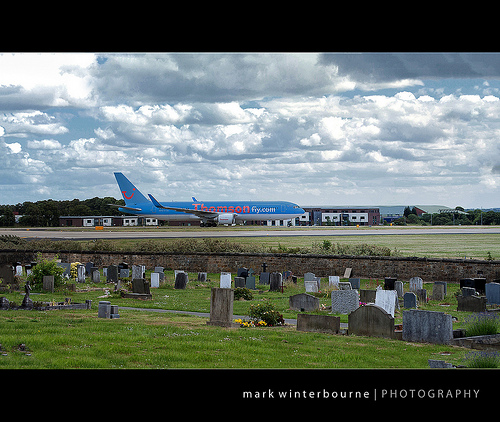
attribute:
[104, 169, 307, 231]
airplane — blue, white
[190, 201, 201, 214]
letter — red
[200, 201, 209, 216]
letter — red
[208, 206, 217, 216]
letter — red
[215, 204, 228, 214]
letter — red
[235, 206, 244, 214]
letter — red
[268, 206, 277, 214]
letter — white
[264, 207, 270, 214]
letter — white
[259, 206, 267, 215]
letter — white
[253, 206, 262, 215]
letter — white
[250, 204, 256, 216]
letter — white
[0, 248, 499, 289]
wall — made of stones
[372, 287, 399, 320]
headstone — white